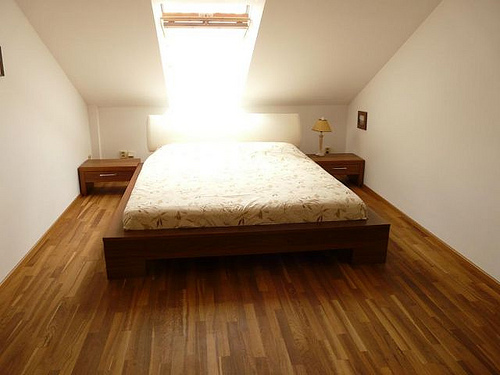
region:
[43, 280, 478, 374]
The floor is wood.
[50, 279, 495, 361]
The floor is brown.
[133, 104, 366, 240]
The bed is white.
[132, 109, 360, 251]
The bed is large.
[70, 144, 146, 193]
The night stand is brown.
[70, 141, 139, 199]
The night stand is wooden.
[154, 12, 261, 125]
The skylight is large.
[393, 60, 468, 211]
The wall is white.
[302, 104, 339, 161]
The lamp is gold.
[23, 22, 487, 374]
The is a bedroom.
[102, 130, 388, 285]
bed sitting on wood floor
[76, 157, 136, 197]
night stand on right side of bed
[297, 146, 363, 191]
night stand on left side of bed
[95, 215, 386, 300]
footboard of wood bed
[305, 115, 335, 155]
beige lamp sitting on night stand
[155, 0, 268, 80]
skylight over the bed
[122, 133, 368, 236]
light bedspread on bed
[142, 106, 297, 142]
white headboard in back of bed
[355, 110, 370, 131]
picture hanging on wall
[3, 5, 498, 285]
white walls of bedroom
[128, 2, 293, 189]
skylight window over the bed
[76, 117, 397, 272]
bed with wooden frame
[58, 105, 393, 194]
wooden night stands on opposite sides of the bed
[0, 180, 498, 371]
brown hardwood floor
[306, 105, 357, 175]
lamp on right nightstand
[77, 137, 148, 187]
no lamp on left nightstand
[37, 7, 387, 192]
slanted ceiling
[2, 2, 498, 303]
white walls and ceiling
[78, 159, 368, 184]
silver hands on nightstand drawers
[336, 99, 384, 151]
small picture on the wall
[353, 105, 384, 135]
red picture on wall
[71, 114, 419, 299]
a bed and two night stands in a bedroom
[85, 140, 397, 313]
a full mattress on a brown bedframe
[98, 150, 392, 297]
a brown wooden bed frame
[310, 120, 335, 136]
top of lamp shade in bedroom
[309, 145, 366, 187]
a brown wooden night stand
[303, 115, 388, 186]
a night stand with a lamp on it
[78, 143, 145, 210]
a brown night stand on the left with little stuff on it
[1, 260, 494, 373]
a brown wooden floor in bedroom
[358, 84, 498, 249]
white walls in a bedroom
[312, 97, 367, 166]
The light is off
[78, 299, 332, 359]
The floor is wooden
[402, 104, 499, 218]
The walls are white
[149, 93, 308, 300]
The bed is made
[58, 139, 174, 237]
The night stand is empty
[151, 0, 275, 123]
The sky light is open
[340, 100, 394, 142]
There is a picture on the wall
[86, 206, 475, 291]
The bed frame is wooden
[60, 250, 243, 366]
The floor is brown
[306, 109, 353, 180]
The lamp is yellow